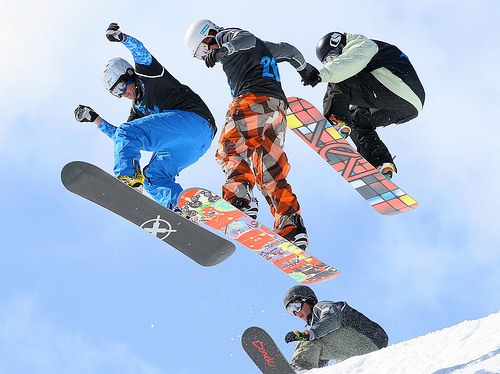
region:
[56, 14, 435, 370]
skiers jumping in air while standing on skis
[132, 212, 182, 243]
white image on bottom of black ski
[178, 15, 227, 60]
helmet on skier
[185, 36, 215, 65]
goggles on skier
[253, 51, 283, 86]
number in blue on back of shirt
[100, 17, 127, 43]
black glove on hand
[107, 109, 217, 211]
blue snow pants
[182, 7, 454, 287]
two skiers holding hands while skiing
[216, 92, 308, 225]
checker patterned ski pants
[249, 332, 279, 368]
red writing on bottom of skiboard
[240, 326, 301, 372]
a black board with red writing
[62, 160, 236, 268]
a black board with white logo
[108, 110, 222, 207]
blue ski pants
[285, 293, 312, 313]
ski goggles on a man's head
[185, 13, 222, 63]
a white helmet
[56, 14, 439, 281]
three snowboarders in the air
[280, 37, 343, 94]
two people holding hands in midair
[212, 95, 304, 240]
brown and orange checkered pants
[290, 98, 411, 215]
checkered snowboard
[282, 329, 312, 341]
a man in a glove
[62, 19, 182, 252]
man jumping on snow board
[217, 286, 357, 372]
man jumping on snow board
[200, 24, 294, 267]
man jumping on snow board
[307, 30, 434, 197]
man jumping on snow board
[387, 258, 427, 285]
white clouds in blue sky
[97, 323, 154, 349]
white clouds in blue sky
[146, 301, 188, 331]
white clouds in blue sky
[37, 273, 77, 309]
white clouds in blue sky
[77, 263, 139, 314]
white clouds in blue sky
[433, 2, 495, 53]
white clouds in blue sky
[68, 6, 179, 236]
snowboarder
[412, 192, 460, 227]
white clouds in blue sky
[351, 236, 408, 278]
white clouds in blue sky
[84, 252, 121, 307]
white clouds in blue sky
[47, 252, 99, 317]
white clouds in blue sky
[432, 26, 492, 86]
white clouds in blue sky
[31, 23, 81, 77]
white clouds in blue sky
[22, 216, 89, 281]
white clouds in blue sky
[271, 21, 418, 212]
man jumping on board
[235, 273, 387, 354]
man jumping in air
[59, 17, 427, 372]
Four snowboarders going off a jump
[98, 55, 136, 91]
A white and gray helmet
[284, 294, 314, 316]
A pair of goggles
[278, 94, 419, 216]
A red, yellow, and blue snow board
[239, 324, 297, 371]
A black and red snow board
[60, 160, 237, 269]
A black and white snow board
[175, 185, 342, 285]
A multi colored snow board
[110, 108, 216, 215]
Bright blue snow pants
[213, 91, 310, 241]
A pair of plaid snow pants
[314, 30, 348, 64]
A black helmet on a snow boarder